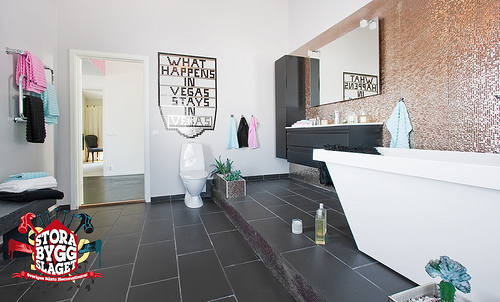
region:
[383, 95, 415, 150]
a towel on the wall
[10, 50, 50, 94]
a pink folded towel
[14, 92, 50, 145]
a black folded towel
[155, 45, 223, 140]
a poster on the wall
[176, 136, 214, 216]
a white porcelain toilet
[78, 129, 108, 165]
a black chair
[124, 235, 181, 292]
a black floor tile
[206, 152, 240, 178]
green plants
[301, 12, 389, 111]
a mirror on the wall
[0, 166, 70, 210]
a stack of towels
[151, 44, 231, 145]
what happens in Vegas sign on wall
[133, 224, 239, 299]
black brick floor tiles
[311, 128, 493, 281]
modern white bathtub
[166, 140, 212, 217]
white porcelain toilet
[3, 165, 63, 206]
three towels on a bench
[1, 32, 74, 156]
three towels hanging on rack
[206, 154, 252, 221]
green plants in rectangular planter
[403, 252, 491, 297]
small green plant in pot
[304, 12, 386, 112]
bathroom mirror on wall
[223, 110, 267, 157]
three hand towels on a rack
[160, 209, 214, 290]
the floor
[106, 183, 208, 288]
the floor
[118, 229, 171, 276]
the floor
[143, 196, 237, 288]
the floor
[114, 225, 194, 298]
the floor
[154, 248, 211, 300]
the floor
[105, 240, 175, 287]
the floor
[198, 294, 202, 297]
the floor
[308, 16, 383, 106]
Mirror on the wall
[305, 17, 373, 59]
Lights on the mirror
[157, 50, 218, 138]
Writing on the wall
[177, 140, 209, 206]
Toilet under the writing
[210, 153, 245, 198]
Plants next to the toilet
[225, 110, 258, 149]
Towels hanging on the wall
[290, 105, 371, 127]
Bathroom goods on the counter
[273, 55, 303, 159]
Cabinet on the wall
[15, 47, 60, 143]
Towels on the rack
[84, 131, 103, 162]
Chair in the other room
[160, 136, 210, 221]
The toilet is white.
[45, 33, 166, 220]
The door is open.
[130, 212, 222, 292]
Tile on the ground.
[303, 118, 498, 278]
A white tub in the bathroom.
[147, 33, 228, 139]
The sign say what happens in Vegas stays in Vegas.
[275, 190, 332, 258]
Containers need the bathtub.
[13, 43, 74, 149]
The tiles are hanging up.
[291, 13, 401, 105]
A mirror hanging on the wall.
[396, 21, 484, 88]
The wall is brown.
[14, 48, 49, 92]
The towel is pink.